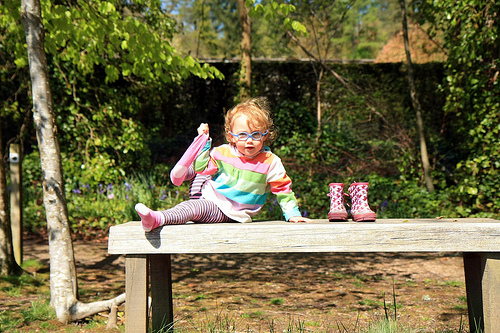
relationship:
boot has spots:
[329, 181, 347, 222] [328, 185, 344, 212]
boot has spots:
[347, 181, 376, 222] [349, 185, 374, 213]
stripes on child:
[192, 137, 302, 224] [127, 97, 307, 231]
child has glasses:
[127, 97, 307, 231] [228, 131, 269, 141]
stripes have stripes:
[160, 161, 241, 225] [160, 157, 234, 228]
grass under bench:
[149, 284, 483, 333] [106, 217, 499, 332]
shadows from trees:
[32, 251, 459, 316] [2, 1, 497, 319]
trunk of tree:
[25, 3, 123, 316] [4, 4, 219, 322]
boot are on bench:
[348, 181, 376, 222] [106, 217, 499, 332]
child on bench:
[127, 97, 307, 231] [106, 217, 499, 332]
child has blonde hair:
[127, 97, 307, 231] [224, 100, 279, 147]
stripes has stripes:
[192, 137, 302, 224] [192, 141, 290, 224]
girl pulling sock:
[127, 97, 307, 231] [168, 129, 208, 187]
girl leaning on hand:
[127, 97, 307, 231] [284, 214, 313, 225]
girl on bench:
[127, 97, 307, 231] [106, 217, 499, 332]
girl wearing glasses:
[127, 97, 307, 231] [228, 131, 269, 141]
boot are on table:
[348, 181, 376, 222] [106, 217, 499, 332]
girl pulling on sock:
[127, 97, 307, 231] [168, 129, 208, 187]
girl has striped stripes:
[127, 97, 307, 231] [160, 161, 241, 225]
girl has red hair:
[127, 97, 307, 231] [224, 100, 279, 147]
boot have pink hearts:
[348, 181, 376, 222] [326, 187, 372, 211]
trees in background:
[2, 1, 497, 319] [4, 4, 498, 269]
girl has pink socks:
[127, 97, 307, 231] [135, 126, 208, 235]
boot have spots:
[348, 181, 376, 222] [324, 182, 375, 214]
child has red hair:
[127, 97, 307, 231] [224, 100, 279, 147]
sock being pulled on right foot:
[168, 129, 208, 187] [170, 165, 187, 188]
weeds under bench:
[149, 284, 483, 333] [106, 217, 499, 332]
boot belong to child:
[348, 181, 376, 222] [127, 97, 307, 231]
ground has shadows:
[3, 200, 496, 331] [32, 251, 459, 316]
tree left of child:
[4, 4, 219, 322] [127, 97, 307, 231]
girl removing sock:
[127, 97, 307, 231] [168, 129, 208, 187]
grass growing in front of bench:
[149, 284, 483, 333] [106, 217, 499, 332]